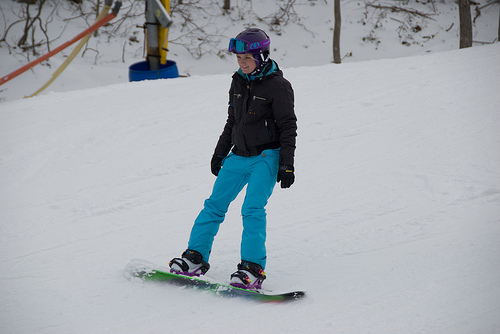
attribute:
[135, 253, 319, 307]
snowboard — green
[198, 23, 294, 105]
girl — smiling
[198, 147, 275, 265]
pants — blue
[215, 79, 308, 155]
jacket — black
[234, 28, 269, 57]
helmet — purple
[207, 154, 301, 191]
gloves — black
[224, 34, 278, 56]
goggles — purple